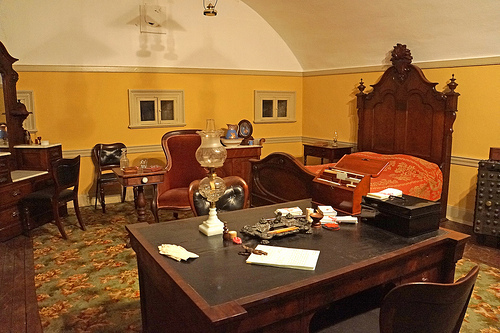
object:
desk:
[124, 198, 471, 333]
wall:
[46, 73, 105, 143]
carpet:
[32, 199, 500, 333]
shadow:
[125, 1, 184, 60]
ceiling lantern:
[202, 0, 218, 17]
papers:
[246, 244, 321, 271]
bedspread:
[303, 151, 443, 202]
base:
[198, 220, 228, 237]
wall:
[16, 4, 135, 61]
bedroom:
[0, 0, 499, 333]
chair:
[308, 265, 480, 333]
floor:
[40, 235, 125, 324]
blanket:
[303, 151, 442, 204]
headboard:
[354, 44, 459, 163]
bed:
[247, 43, 474, 227]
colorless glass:
[195, 129, 227, 202]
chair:
[18, 154, 88, 241]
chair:
[91, 138, 128, 213]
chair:
[142, 128, 210, 223]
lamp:
[194, 130, 227, 237]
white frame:
[127, 88, 187, 129]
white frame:
[253, 90, 297, 124]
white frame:
[16, 89, 38, 133]